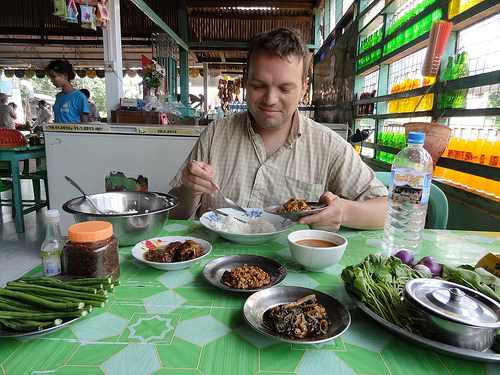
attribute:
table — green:
[6, 192, 433, 339]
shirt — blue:
[50, 88, 90, 125]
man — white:
[163, 24, 388, 232]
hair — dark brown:
[245, 27, 307, 86]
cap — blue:
[404, 128, 425, 145]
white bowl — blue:
[199, 205, 297, 242]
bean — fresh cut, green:
[1, 287, 83, 312]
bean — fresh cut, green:
[9, 277, 104, 301]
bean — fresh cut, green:
[5, 320, 40, 332]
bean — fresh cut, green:
[4, 297, 26, 309]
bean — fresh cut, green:
[82, 273, 112, 287]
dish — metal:
[404, 271, 499, 356]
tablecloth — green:
[157, 322, 229, 348]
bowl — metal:
[64, 187, 174, 244]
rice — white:
[204, 212, 276, 234]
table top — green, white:
[22, 205, 451, 372]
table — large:
[3, 229, 498, 373]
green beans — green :
[1, 275, 122, 329]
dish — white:
[127, 222, 216, 268]